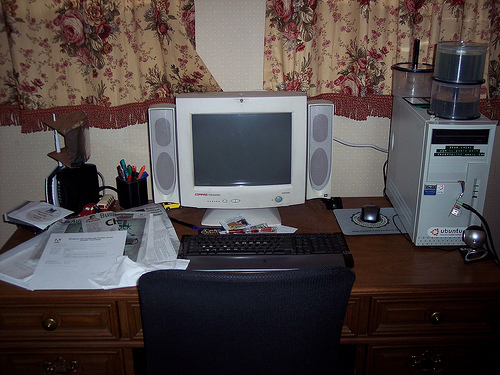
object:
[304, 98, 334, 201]
speaker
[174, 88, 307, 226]
computer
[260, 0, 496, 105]
curtain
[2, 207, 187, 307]
papers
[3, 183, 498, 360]
desk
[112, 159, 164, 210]
pens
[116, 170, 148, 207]
holder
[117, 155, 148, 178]
pencils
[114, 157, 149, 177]
pens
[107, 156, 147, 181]
pens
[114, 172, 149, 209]
black container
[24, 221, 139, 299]
papers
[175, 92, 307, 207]
screen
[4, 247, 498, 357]
desk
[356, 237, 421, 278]
desk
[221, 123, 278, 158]
screen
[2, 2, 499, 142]
curtains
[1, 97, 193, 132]
fringe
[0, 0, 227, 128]
curtains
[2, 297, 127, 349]
drawer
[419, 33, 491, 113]
cd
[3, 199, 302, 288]
papers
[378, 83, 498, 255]
computer tower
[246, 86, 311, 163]
monitor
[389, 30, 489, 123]
cd cases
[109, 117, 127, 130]
edge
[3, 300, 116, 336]
drawer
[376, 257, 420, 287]
top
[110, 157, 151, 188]
pens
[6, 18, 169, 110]
curtain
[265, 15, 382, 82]
curtain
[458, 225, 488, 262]
webcam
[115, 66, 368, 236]
monitor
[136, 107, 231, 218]
speakers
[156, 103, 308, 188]
computer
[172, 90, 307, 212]
computer monitor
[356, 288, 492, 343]
drawer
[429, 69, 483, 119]
case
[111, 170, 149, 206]
cup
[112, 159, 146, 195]
pencils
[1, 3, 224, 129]
blanket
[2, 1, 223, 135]
window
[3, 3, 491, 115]
flowers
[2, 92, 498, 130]
fringe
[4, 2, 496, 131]
windows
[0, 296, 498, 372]
drawers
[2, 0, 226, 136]
curtain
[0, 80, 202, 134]
fringes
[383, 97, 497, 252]
computer tower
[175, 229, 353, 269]
keyboard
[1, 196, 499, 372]
desk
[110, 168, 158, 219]
container